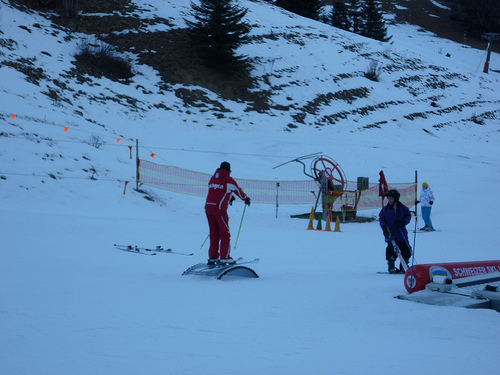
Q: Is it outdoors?
A: Yes, it is outdoors.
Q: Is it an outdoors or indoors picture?
A: It is outdoors.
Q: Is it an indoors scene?
A: No, it is outdoors.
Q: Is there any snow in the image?
A: Yes, there is snow.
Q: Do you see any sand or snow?
A: Yes, there is snow.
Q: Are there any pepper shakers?
A: No, there are no pepper shakers.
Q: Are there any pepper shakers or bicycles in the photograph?
A: No, there are no pepper shakers or bicycles.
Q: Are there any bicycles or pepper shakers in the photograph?
A: No, there are no pepper shakers or bicycles.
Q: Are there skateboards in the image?
A: No, there are no skateboards.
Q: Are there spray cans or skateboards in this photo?
A: No, there are no skateboards or spray cans.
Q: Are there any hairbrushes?
A: No, there are no hairbrushes.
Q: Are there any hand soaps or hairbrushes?
A: No, there are no hairbrushes or hand soaps.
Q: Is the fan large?
A: Yes, the fan is large.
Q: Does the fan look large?
A: Yes, the fan is large.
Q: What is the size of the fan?
A: The fan is large.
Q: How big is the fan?
A: The fan is large.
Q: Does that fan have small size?
A: No, the fan is large.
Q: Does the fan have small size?
A: No, the fan is large.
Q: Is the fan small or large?
A: The fan is large.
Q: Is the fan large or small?
A: The fan is large.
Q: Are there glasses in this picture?
A: No, there are no glasses.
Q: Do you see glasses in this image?
A: No, there are no glasses.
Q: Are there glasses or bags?
A: No, there are no glasses or bags.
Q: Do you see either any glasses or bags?
A: No, there are no glasses or bags.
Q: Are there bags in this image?
A: No, there are no bags.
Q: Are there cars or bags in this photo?
A: No, there are no bags or cars.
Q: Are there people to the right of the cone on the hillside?
A: Yes, there is a person to the right of the cone.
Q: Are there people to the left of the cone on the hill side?
A: No, the person is to the right of the safety cone.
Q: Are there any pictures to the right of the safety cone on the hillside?
A: No, there is a person to the right of the traffic cone.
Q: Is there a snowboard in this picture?
A: No, there are no snowboards.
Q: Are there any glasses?
A: No, there are no glasses.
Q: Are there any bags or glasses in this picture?
A: No, there are no glasses or bags.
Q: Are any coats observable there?
A: Yes, there is a coat.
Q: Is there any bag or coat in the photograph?
A: Yes, there is a coat.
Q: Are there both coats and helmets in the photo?
A: Yes, there are both a coat and a helmet.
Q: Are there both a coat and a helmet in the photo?
A: Yes, there are both a coat and a helmet.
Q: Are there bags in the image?
A: No, there are no bags.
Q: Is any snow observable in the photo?
A: Yes, there is snow.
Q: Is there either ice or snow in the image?
A: Yes, there is snow.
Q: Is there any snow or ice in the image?
A: Yes, there is snow.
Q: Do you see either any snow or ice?
A: Yes, there is snow.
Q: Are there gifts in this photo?
A: No, there are no gifts.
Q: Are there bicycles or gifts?
A: No, there are no gifts or bicycles.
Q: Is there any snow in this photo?
A: Yes, there is snow.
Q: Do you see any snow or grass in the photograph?
A: Yes, there is snow.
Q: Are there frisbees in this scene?
A: No, there are no frisbees.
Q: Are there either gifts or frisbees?
A: No, there are no frisbees or gifts.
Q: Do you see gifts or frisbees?
A: No, there are no frisbees or gifts.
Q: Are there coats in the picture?
A: Yes, there is a coat.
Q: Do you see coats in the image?
A: Yes, there is a coat.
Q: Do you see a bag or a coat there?
A: Yes, there is a coat.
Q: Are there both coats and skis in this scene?
A: Yes, there are both a coat and skis.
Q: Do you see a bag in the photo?
A: No, there are no bags.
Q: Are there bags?
A: No, there are no bags.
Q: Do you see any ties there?
A: No, there are no ties.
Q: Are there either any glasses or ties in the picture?
A: No, there are no ties or glasses.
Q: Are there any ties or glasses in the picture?
A: No, there are no ties or glasses.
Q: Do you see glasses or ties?
A: No, there are no ties or glasses.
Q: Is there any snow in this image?
A: Yes, there is snow.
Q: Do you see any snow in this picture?
A: Yes, there is snow.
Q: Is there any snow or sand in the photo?
A: Yes, there is snow.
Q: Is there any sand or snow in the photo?
A: Yes, there is snow.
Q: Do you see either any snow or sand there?
A: Yes, there is snow.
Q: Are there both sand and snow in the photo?
A: No, there is snow but no sand.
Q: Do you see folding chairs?
A: No, there are no folding chairs.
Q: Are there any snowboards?
A: No, there are no snowboards.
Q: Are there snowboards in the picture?
A: No, there are no snowboards.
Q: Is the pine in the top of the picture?
A: Yes, the pine is in the top of the image.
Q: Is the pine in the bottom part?
A: No, the pine is in the top of the image.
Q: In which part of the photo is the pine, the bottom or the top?
A: The pine is in the top of the image.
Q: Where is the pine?
A: The pine is on the hillside.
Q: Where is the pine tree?
A: The pine is on the hillside.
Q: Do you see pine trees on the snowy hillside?
A: Yes, there is a pine tree on the hillside.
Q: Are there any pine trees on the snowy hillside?
A: Yes, there is a pine tree on the hillside.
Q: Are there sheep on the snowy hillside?
A: No, there is a pine tree on the hill side.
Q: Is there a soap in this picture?
A: No, there are no soaps.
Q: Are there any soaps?
A: No, there are no soaps.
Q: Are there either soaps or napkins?
A: No, there are no soaps or napkins.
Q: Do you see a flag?
A: Yes, there is a flag.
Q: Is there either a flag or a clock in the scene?
A: Yes, there is a flag.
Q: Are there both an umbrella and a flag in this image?
A: No, there is a flag but no umbrellas.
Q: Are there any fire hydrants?
A: No, there are no fire hydrants.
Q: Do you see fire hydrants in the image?
A: No, there are no fire hydrants.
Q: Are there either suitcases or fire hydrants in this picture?
A: No, there are no fire hydrants or suitcases.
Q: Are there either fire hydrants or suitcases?
A: No, there are no fire hydrants or suitcases.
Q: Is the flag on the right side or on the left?
A: The flag is on the left of the image.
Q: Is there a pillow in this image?
A: No, there are no pillows.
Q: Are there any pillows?
A: No, there are no pillows.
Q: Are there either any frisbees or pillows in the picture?
A: No, there are no pillows or frisbees.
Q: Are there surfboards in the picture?
A: No, there are no surfboards.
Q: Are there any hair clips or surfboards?
A: No, there are no surfboards or hair clips.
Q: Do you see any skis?
A: Yes, there are skis.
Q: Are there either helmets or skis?
A: Yes, there are skis.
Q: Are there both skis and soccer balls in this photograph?
A: No, there are skis but no soccer balls.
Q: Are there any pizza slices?
A: No, there are no pizza slices.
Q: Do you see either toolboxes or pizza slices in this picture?
A: No, there are no pizza slices or toolboxes.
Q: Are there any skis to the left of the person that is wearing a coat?
A: Yes, there are skis to the left of the person.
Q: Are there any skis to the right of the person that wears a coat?
A: No, the skis are to the left of the person.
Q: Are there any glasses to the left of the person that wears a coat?
A: No, there are skis to the left of the person.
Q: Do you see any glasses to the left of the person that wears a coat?
A: No, there are skis to the left of the person.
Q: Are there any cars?
A: No, there are no cars.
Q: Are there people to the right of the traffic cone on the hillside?
A: Yes, there is a person to the right of the traffic cone.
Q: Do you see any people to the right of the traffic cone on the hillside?
A: Yes, there is a person to the right of the traffic cone.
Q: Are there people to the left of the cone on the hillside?
A: No, the person is to the right of the traffic cone.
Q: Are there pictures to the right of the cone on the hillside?
A: No, there is a person to the right of the traffic cone.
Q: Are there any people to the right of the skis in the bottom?
A: Yes, there is a person to the right of the skis.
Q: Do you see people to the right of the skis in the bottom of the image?
A: Yes, there is a person to the right of the skis.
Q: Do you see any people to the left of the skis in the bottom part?
A: No, the person is to the right of the skis.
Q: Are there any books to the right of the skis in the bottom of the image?
A: No, there is a person to the right of the skis.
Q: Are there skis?
A: Yes, there are skis.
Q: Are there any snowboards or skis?
A: Yes, there are skis.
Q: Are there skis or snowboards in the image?
A: Yes, there are skis.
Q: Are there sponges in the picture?
A: No, there are no sponges.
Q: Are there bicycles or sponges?
A: No, there are no sponges or bicycles.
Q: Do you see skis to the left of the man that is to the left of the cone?
A: Yes, there are skis to the left of the man.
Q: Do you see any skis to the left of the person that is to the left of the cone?
A: Yes, there are skis to the left of the man.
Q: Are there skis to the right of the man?
A: No, the skis are to the left of the man.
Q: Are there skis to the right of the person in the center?
A: No, the skis are to the left of the man.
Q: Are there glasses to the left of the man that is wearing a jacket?
A: No, there are skis to the left of the man.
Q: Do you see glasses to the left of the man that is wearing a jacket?
A: No, there are skis to the left of the man.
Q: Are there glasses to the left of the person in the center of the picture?
A: No, there are skis to the left of the man.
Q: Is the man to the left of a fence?
A: No, the man is to the left of a cone.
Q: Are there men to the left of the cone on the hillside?
A: Yes, there is a man to the left of the cone.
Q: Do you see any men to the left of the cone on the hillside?
A: Yes, there is a man to the left of the cone.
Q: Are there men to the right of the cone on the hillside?
A: No, the man is to the left of the traffic cone.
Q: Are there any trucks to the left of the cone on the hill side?
A: No, there is a man to the left of the traffic cone.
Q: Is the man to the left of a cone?
A: Yes, the man is to the left of a cone.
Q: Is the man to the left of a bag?
A: No, the man is to the left of a cone.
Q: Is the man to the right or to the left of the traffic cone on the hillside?
A: The man is to the left of the traffic cone.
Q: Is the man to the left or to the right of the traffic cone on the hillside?
A: The man is to the left of the traffic cone.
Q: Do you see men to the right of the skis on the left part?
A: Yes, there is a man to the right of the skis.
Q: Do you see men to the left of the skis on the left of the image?
A: No, the man is to the right of the skis.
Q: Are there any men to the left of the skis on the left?
A: No, the man is to the right of the skis.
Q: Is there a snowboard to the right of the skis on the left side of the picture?
A: No, there is a man to the right of the skis.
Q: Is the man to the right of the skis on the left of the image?
A: Yes, the man is to the right of the skis.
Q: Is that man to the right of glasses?
A: No, the man is to the right of the skis.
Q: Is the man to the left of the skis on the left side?
A: No, the man is to the right of the skis.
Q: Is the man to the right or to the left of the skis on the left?
A: The man is to the right of the skis.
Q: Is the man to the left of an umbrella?
A: No, the man is to the left of a cone.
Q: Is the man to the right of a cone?
A: No, the man is to the left of a cone.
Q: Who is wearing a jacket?
A: The man is wearing a jacket.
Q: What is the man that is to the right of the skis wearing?
A: The man is wearing a jacket.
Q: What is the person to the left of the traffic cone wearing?
A: The man is wearing a jacket.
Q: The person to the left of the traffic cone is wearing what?
A: The man is wearing a jacket.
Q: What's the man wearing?
A: The man is wearing a jacket.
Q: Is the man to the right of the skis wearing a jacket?
A: Yes, the man is wearing a jacket.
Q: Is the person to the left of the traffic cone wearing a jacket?
A: Yes, the man is wearing a jacket.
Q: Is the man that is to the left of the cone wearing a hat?
A: No, the man is wearing a jacket.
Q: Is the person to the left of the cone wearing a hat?
A: No, the man is wearing a jacket.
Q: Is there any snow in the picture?
A: Yes, there is snow.